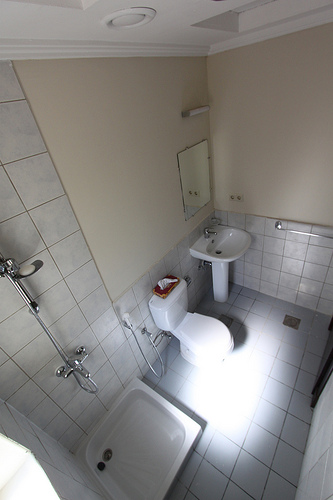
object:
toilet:
[147, 262, 236, 378]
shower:
[0, 225, 104, 409]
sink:
[189, 212, 258, 272]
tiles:
[267, 345, 305, 393]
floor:
[161, 298, 305, 487]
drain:
[276, 306, 306, 335]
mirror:
[169, 131, 233, 224]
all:
[0, 0, 332, 498]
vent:
[189, 0, 333, 42]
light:
[169, 92, 233, 126]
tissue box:
[149, 258, 185, 305]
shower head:
[0, 240, 48, 297]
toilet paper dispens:
[177, 268, 197, 289]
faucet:
[198, 215, 223, 244]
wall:
[3, 60, 204, 318]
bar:
[268, 207, 333, 257]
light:
[96, 0, 163, 57]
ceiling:
[0, 0, 331, 61]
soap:
[86, 456, 110, 477]